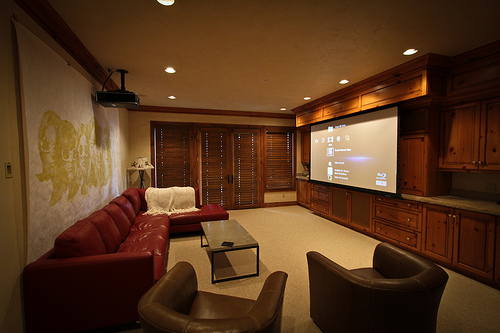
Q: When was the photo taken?
A: Night time.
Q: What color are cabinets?
A: Brown.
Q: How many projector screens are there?
A: One.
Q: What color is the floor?
A: White.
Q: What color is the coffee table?
A: Gray.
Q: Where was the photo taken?
A: Entertainment room.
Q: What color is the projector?
A: Black.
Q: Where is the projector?
A: Above the red sofa.